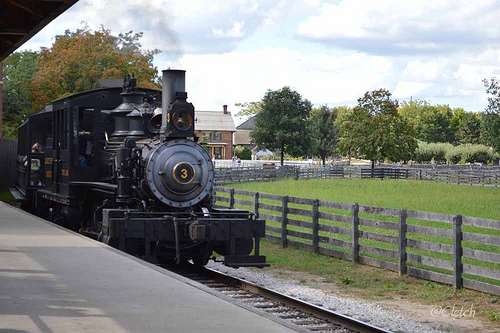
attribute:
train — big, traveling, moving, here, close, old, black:
[38, 72, 269, 256]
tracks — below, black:
[227, 275, 311, 326]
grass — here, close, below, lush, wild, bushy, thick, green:
[348, 178, 412, 220]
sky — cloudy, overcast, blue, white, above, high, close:
[211, 2, 446, 82]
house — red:
[195, 100, 236, 167]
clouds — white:
[184, 47, 353, 94]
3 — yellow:
[172, 158, 199, 188]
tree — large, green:
[248, 80, 315, 165]